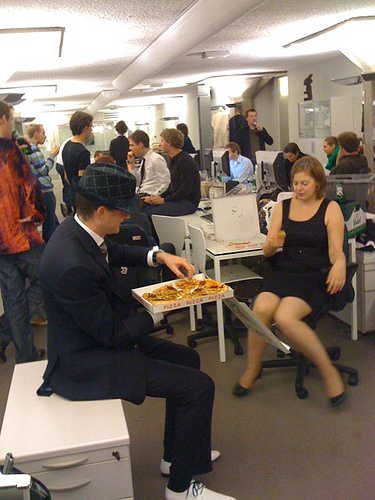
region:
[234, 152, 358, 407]
woman sitting down in office chair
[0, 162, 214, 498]
man is sitting on filing cabnet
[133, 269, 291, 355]
holding a box of pizza pie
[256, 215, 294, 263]
girl is eating a piece of pizza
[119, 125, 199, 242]
men setting on desk eating pizza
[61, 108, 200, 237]
men deeply immersed in conversation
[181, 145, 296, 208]
line of computers setting at desks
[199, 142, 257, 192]
man is using computer during office party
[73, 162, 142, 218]
wearing a hat on head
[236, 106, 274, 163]
man is eating while walking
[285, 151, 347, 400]
woman wearing black dress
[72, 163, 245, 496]
man wearing a hat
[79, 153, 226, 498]
man eating a pizza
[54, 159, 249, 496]
man wearing black jacket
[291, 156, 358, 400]
woman wearing black shoes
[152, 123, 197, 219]
man wearing black shirt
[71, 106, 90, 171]
man wearing black shirt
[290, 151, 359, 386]
woman sitting in a chair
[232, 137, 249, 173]
man wearing blue shirt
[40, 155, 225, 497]
man wearing white shoes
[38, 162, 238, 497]
Man holding a box of pizza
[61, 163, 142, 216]
Black hat on man's head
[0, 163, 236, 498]
Man sitting on a white trunk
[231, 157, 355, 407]
Woman seated in chair wearing sleeveless black dress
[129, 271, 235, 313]
Pizza in a box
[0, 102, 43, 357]
Man in orange jacket and blue jeans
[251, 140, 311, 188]
Man seated in front of computer screen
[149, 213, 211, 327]
Two white chairs by the table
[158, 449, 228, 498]
White shoes on man's feet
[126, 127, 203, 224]
Two men sitting on a table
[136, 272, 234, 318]
pepperoni pizza in pizza box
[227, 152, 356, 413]
lady in black dress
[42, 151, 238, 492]
guy in black suit eating pizza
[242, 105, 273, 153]
guy in black coat drinking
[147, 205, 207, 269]
two white computer chairs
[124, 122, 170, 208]
guy in white dress shirt with tie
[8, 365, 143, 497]
white portable dresser with key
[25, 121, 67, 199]
guy in blue green black sweater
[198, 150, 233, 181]
back side computer monitor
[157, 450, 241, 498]
two white dress shoes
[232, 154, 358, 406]
a woman sitting on the rolling chair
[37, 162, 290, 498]
a guy taking out a pizza from the box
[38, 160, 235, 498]
a guy in black dress is sitting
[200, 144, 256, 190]
a guy sitting in front of a computer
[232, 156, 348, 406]
a woman holding a slice of pizza in her right hand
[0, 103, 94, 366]
people are standing in the floor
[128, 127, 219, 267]
two people sitting on the table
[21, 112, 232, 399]
people are eating in groups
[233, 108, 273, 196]
a guy in his black jacket is standing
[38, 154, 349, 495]
two people sitting and enjoying the pizza